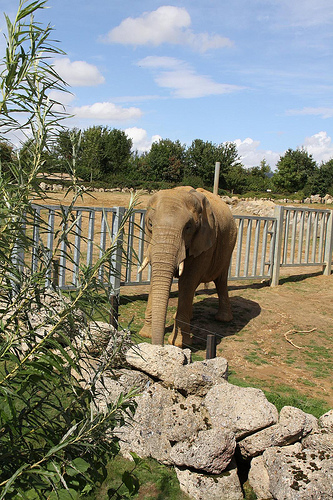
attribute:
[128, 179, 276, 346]
elephant — young, brown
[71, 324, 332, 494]
boulders — grouped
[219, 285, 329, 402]
ground — dirt-covered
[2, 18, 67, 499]
bush — large, leafy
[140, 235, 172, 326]
trunk — wrinkled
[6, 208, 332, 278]
fence — grey, metal, white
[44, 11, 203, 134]
clouds — white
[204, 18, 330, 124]
sky — blue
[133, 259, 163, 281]
tusk — small, white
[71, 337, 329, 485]
rocks — large, big, grey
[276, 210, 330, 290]
gate — grey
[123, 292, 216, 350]
fence — wire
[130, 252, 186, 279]
tusks — white